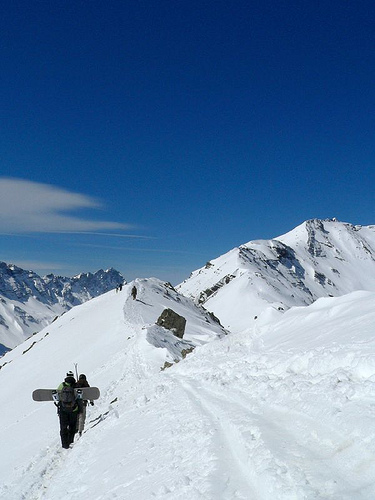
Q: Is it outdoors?
A: Yes, it is outdoors.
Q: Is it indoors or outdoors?
A: It is outdoors.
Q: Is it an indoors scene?
A: No, it is outdoors.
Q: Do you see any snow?
A: Yes, there is snow.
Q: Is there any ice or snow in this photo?
A: Yes, there is snow.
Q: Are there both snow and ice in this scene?
A: Yes, there are both snow and ice.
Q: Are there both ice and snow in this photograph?
A: Yes, there are both snow and ice.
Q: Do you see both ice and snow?
A: Yes, there are both snow and ice.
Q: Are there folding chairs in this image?
A: No, there are no folding chairs.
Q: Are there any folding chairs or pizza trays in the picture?
A: No, there are no folding chairs or pizza trays.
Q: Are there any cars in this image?
A: No, there are no cars.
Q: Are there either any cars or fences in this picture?
A: No, there are no cars or fences.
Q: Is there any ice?
A: Yes, there is ice.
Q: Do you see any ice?
A: Yes, there is ice.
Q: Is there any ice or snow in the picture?
A: Yes, there is ice.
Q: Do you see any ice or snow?
A: Yes, there is ice.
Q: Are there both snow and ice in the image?
A: Yes, there are both ice and snow.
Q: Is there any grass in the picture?
A: No, there is no grass.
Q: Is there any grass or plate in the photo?
A: No, there are no grass or plates.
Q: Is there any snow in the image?
A: Yes, there is snow.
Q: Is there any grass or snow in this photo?
A: Yes, there is snow.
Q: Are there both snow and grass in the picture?
A: No, there is snow but no grass.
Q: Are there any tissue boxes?
A: No, there are no tissue boxes.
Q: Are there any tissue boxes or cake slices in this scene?
A: No, there are no tissue boxes or cake slices.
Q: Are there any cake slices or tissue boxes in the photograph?
A: No, there are no tissue boxes or cake slices.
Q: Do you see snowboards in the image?
A: Yes, there is a snowboard.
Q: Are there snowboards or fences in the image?
A: Yes, there is a snowboard.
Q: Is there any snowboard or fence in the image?
A: Yes, there is a snowboard.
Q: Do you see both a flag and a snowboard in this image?
A: No, there is a snowboard but no flags.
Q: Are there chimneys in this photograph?
A: No, there are no chimneys.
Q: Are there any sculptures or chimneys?
A: No, there are no chimneys or sculptures.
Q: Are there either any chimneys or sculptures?
A: No, there are no chimneys or sculptures.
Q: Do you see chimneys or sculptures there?
A: No, there are no chimneys or sculptures.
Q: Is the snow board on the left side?
A: Yes, the snow board is on the left of the image.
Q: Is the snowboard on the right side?
A: No, the snowboard is on the left of the image.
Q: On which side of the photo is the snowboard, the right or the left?
A: The snowboard is on the left of the image.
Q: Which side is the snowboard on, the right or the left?
A: The snowboard is on the left of the image.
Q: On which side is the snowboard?
A: The snowboard is on the left of the image.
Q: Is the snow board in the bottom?
A: Yes, the snow board is in the bottom of the image.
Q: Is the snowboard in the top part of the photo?
A: No, the snowboard is in the bottom of the image.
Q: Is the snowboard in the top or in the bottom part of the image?
A: The snowboard is in the bottom of the image.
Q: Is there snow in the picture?
A: Yes, there is snow.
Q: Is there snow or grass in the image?
A: Yes, there is snow.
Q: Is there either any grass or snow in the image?
A: Yes, there is snow.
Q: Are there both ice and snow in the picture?
A: Yes, there are both snow and ice.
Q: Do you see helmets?
A: No, there are no helmets.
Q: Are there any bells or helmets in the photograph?
A: No, there are no helmets or bells.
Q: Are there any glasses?
A: No, there are no glasses.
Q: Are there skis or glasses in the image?
A: No, there are no glasses or skis.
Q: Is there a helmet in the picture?
A: No, there are no helmets.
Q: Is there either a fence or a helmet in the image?
A: No, there are no helmets or fences.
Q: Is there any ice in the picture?
A: Yes, there is ice.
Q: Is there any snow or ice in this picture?
A: Yes, there is ice.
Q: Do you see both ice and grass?
A: No, there is ice but no grass.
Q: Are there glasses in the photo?
A: No, there are no glasses.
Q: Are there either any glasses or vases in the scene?
A: No, there are no glasses or vases.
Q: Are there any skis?
A: No, there are no skis.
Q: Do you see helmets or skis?
A: No, there are no skis or helmets.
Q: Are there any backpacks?
A: Yes, there is a backpack.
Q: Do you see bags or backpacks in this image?
A: Yes, there is a backpack.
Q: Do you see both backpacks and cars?
A: No, there is a backpack but no cars.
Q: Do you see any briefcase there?
A: No, there are no briefcases.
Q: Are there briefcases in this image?
A: No, there are no briefcases.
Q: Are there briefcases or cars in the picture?
A: No, there are no briefcases or cars.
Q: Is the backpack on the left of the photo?
A: Yes, the backpack is on the left of the image.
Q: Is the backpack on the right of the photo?
A: No, the backpack is on the left of the image.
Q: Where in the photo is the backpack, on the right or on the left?
A: The backpack is on the left of the image.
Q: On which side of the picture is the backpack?
A: The backpack is on the left of the image.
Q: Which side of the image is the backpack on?
A: The backpack is on the left of the image.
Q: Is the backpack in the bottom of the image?
A: Yes, the backpack is in the bottom of the image.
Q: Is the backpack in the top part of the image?
A: No, the backpack is in the bottom of the image.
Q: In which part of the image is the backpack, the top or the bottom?
A: The backpack is in the bottom of the image.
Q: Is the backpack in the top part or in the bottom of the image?
A: The backpack is in the bottom of the image.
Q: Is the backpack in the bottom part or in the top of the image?
A: The backpack is in the bottom of the image.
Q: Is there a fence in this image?
A: No, there are no fences.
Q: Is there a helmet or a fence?
A: No, there are no fences or helmets.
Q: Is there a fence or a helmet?
A: No, there are no fences or helmets.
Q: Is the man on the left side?
A: Yes, the man is on the left of the image.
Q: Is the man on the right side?
A: No, the man is on the left of the image.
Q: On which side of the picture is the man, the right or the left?
A: The man is on the left of the image.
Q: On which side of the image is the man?
A: The man is on the left of the image.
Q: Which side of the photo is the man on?
A: The man is on the left of the image.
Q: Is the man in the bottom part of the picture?
A: Yes, the man is in the bottom of the image.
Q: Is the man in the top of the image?
A: No, the man is in the bottom of the image.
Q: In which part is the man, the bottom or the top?
A: The man is in the bottom of the image.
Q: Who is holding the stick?
A: The man is holding the stick.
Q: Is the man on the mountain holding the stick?
A: Yes, the man is holding the stick.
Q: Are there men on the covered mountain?
A: Yes, there is a man on the mountain.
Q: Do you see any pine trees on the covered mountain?
A: No, there is a man on the mountain.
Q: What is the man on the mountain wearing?
A: The man is wearing trousers.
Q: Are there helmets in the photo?
A: No, there are no helmets.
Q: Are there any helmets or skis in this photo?
A: No, there are no helmets or skis.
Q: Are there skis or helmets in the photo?
A: No, there are no helmets or skis.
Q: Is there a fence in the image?
A: No, there are no fences.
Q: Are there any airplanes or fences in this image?
A: No, there are no fences or airplanes.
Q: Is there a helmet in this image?
A: No, there are no helmets.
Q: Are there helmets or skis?
A: No, there are no helmets or skis.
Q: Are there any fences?
A: No, there are no fences.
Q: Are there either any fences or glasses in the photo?
A: No, there are no fences or glasses.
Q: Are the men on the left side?
A: Yes, the men are on the left of the image.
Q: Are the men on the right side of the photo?
A: No, the men are on the left of the image.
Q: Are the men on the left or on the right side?
A: The men are on the left of the image.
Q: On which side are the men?
A: The men are on the left of the image.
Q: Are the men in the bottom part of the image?
A: Yes, the men are in the bottom of the image.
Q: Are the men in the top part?
A: No, the men are in the bottom of the image.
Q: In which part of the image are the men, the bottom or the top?
A: The men are in the bottom of the image.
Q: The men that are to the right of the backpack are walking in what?
A: The men are walking in the ice.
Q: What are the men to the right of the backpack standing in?
A: The men are standing in the ice.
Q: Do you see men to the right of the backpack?
A: Yes, there are men to the right of the backpack.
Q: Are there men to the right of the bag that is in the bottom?
A: Yes, there are men to the right of the backpack.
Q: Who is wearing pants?
A: The men are wearing pants.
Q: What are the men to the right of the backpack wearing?
A: The men are wearing pants.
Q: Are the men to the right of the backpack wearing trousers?
A: Yes, the men are wearing trousers.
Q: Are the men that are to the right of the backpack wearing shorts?
A: No, the men are wearing trousers.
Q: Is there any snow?
A: Yes, there is snow.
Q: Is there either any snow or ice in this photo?
A: Yes, there is snow.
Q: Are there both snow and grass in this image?
A: No, there is snow but no grass.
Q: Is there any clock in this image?
A: No, there are no clocks.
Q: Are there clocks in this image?
A: No, there are no clocks.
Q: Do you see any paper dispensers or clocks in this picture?
A: No, there are no clocks or paper dispensers.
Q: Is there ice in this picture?
A: Yes, there is ice.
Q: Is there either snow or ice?
A: Yes, there is ice.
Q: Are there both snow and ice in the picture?
A: Yes, there are both ice and snow.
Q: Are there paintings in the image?
A: No, there are no paintings.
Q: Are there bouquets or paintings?
A: No, there are no paintings or bouquets.